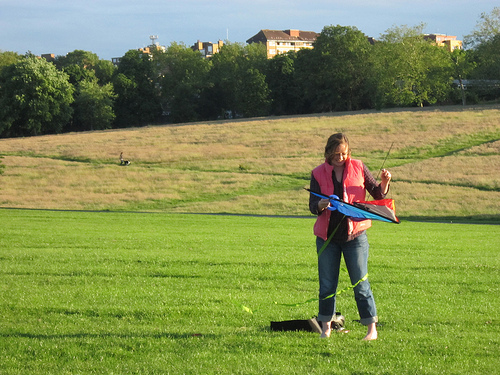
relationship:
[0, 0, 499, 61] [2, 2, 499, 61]
cloud in sky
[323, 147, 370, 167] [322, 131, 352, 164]
hair on head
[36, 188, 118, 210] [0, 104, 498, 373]
dead grass on ground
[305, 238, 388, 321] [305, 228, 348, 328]
pants on leg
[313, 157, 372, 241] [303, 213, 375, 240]
vest on waist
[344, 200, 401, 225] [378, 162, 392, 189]
kite in hand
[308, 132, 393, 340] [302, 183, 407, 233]
woman holding kite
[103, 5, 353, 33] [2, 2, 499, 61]
cloud in sky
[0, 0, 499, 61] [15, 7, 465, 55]
cloud in sky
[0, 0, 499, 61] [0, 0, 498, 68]
cloud in sky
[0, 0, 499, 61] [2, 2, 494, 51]
cloud in sky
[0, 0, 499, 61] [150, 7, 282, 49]
cloud in sky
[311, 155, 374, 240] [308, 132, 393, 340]
vest worn by woman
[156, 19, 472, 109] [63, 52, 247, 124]
buildings behind trees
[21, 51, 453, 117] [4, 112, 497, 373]
tree line behind field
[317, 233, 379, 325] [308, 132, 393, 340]
pants worn by woman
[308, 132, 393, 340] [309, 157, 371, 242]
woman wearing vest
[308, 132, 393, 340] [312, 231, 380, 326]
woman wearing jeans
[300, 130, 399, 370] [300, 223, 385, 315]
woman in jeans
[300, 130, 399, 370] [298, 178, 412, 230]
woman holding kite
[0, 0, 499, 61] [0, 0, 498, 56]
cloud in sky